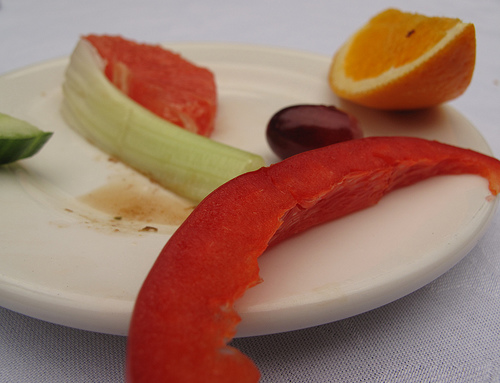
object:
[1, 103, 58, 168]
cucumber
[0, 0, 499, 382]
cloth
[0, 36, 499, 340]
white plate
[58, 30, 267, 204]
celery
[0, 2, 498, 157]
wall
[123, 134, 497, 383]
food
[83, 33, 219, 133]
food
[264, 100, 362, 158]
food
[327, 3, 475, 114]
food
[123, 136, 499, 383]
food hangs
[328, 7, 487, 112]
orange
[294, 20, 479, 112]
peel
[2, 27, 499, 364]
plate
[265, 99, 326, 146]
grape